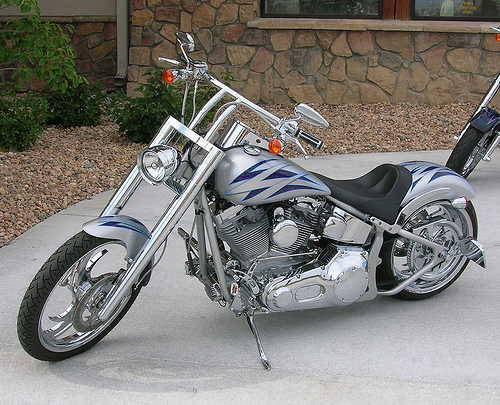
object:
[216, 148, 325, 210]
designs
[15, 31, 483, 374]
bike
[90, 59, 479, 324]
frame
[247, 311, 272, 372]
kick stand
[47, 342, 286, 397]
shadow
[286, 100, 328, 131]
mirror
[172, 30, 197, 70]
mirror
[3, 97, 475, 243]
rocks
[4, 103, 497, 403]
ground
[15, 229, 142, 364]
tire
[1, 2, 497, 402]
picture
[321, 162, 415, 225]
seat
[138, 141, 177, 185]
headlight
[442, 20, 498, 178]
bike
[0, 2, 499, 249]
background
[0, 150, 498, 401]
driveway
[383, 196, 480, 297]
tire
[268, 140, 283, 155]
light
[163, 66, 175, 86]
light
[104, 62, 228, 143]
plant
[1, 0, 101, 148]
plant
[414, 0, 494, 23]
sign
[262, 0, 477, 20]
window